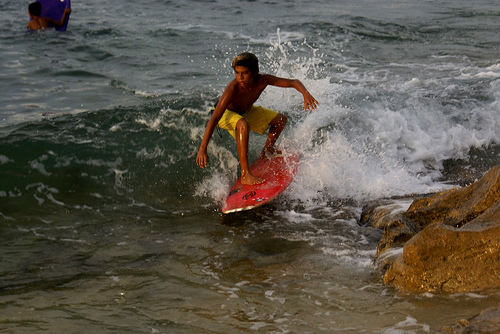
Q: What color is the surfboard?
A: Red.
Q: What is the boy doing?
A: Surfing.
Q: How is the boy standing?
A: Bending.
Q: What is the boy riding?
A: Surfboard.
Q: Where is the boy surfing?
A: Ocean.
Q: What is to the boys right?
A: Rock.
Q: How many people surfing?
A: One.